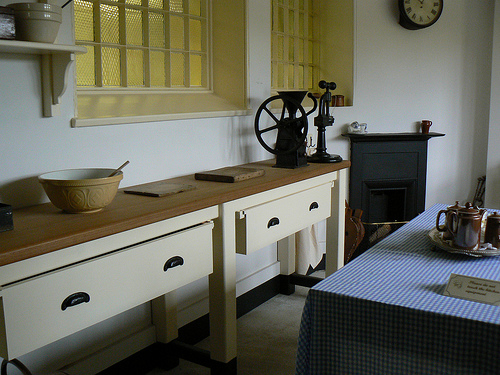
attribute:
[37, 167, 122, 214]
bowl — tan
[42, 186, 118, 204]
design — pretty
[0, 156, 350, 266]
top — wooden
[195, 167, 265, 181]
board — large, dark, brown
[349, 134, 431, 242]
fireplace — old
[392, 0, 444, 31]
clock — round, black, analog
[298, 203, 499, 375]
tablecloth — blue, white, checked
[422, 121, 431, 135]
cup — small, brown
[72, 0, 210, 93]
window — square, yellow